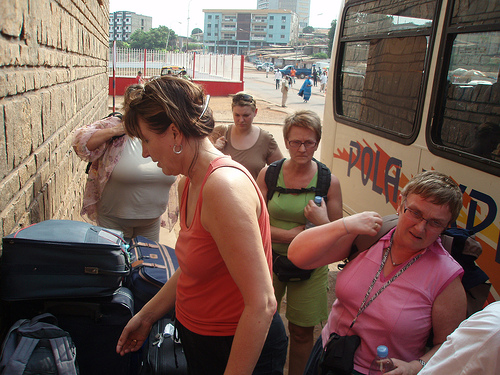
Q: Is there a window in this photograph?
A: Yes, there is a window.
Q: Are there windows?
A: Yes, there is a window.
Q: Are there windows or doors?
A: Yes, there is a window.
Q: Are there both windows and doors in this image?
A: No, there is a window but no doors.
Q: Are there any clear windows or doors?
A: Yes, there is a clear window.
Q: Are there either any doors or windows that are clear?
A: Yes, the window is clear.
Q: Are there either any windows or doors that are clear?
A: Yes, the window is clear.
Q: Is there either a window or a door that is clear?
A: Yes, the window is clear.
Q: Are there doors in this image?
A: No, there are no doors.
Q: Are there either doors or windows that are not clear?
A: No, there is a window but it is clear.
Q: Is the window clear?
A: Yes, the window is clear.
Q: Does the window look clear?
A: Yes, the window is clear.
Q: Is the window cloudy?
A: No, the window is clear.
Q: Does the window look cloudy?
A: No, the window is clear.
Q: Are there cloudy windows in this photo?
A: No, there is a window but it is clear.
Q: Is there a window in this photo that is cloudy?
A: No, there is a window but it is clear.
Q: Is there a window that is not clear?
A: No, there is a window but it is clear.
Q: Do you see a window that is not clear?
A: No, there is a window but it is clear.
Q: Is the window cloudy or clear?
A: The window is clear.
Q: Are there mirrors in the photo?
A: No, there are no mirrors.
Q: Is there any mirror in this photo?
A: No, there are no mirrors.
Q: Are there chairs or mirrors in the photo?
A: No, there are no mirrors or chairs.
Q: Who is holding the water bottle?
A: The passengers are holding the water bottle.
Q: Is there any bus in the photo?
A: Yes, there is a bus.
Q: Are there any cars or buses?
A: Yes, there is a bus.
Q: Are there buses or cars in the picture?
A: Yes, there is a bus.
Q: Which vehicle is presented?
A: The vehicle is a bus.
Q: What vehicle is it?
A: The vehicle is a bus.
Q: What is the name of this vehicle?
A: This is a bus.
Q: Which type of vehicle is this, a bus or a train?
A: This is a bus.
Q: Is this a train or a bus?
A: This is a bus.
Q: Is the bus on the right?
A: Yes, the bus is on the right of the image.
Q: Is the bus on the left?
A: No, the bus is on the right of the image.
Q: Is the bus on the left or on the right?
A: The bus is on the right of the image.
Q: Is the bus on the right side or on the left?
A: The bus is on the right of the image.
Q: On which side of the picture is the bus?
A: The bus is on the right of the image.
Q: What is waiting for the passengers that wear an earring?
A: The bus is waiting for the passengers.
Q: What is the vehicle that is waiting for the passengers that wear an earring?
A: The vehicle is a bus.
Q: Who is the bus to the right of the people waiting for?
A: The bus is waiting for the passengers.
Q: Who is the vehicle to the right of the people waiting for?
A: The bus is waiting for the passengers.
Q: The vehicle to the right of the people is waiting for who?
A: The bus is waiting for the passengers.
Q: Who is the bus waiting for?
A: The bus is waiting for the passengers.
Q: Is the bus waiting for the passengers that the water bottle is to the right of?
A: Yes, the bus is waiting for the passengers.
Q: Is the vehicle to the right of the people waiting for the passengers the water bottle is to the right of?
A: Yes, the bus is waiting for the passengers.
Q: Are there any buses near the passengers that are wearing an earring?
A: Yes, there is a bus near the passengers.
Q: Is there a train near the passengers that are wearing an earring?
A: No, there is a bus near the passengers.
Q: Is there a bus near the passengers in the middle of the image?
A: Yes, there is a bus near the passengers.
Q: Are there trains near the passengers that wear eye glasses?
A: No, there is a bus near the passengers.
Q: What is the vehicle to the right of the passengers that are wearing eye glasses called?
A: The vehicle is a bus.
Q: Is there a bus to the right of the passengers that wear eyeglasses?
A: Yes, there is a bus to the right of the passengers.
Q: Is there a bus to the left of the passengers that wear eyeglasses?
A: No, the bus is to the right of the passengers.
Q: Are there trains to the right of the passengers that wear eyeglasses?
A: No, there is a bus to the right of the passengers.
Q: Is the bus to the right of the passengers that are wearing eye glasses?
A: Yes, the bus is to the right of the passengers.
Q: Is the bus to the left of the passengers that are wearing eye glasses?
A: No, the bus is to the right of the passengers.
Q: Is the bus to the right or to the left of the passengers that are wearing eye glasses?
A: The bus is to the right of the passengers.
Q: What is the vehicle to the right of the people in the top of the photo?
A: The vehicle is a bus.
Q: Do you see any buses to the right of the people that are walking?
A: Yes, there is a bus to the right of the people.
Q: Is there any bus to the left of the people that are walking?
A: No, the bus is to the right of the people.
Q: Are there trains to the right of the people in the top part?
A: No, there is a bus to the right of the people.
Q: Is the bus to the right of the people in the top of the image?
A: Yes, the bus is to the right of the people.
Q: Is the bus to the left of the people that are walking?
A: No, the bus is to the right of the people.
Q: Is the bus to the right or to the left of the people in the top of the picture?
A: The bus is to the right of the people.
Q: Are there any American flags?
A: No, there are no American flags.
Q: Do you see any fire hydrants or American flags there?
A: No, there are no American flags or fire hydrants.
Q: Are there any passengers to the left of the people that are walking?
A: Yes, there are passengers to the left of the people.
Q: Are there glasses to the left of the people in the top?
A: No, there are passengers to the left of the people.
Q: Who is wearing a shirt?
A: The passengers are wearing a shirt.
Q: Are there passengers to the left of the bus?
A: Yes, there are passengers to the left of the bus.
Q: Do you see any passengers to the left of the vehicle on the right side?
A: Yes, there are passengers to the left of the bus.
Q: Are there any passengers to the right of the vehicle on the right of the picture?
A: No, the passengers are to the left of the bus.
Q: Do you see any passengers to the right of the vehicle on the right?
A: No, the passengers are to the left of the bus.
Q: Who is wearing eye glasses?
A: The passengers are wearing eye glasses.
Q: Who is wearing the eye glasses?
A: The passengers are wearing eye glasses.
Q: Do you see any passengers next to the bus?
A: Yes, there are passengers next to the bus.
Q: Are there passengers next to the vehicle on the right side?
A: Yes, there are passengers next to the bus.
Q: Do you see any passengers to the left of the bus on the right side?
A: Yes, there are passengers to the left of the bus.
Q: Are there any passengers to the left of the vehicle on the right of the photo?
A: Yes, there are passengers to the left of the bus.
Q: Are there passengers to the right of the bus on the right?
A: No, the passengers are to the left of the bus.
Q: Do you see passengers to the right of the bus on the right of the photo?
A: No, the passengers are to the left of the bus.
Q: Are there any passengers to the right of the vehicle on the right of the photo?
A: No, the passengers are to the left of the bus.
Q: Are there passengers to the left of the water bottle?
A: Yes, there are passengers to the left of the water bottle.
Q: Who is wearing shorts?
A: The passengers are wearing shorts.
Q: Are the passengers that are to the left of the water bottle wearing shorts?
A: Yes, the passengers are wearing shorts.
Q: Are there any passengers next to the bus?
A: Yes, there are passengers next to the bus.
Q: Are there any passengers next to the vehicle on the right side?
A: Yes, there are passengers next to the bus.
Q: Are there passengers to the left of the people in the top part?
A: Yes, there are passengers to the left of the people.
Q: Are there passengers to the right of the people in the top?
A: No, the passengers are to the left of the people.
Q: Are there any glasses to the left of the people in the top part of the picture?
A: No, there are passengers to the left of the people.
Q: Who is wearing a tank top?
A: The passengers are wearing a tank top.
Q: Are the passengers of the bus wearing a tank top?
A: Yes, the passengers are wearing a tank top.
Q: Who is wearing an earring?
A: The passengers are wearing an earring.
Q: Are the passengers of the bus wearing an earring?
A: Yes, the passengers are wearing an earring.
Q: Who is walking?
A: The people are walking.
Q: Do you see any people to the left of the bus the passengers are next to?
A: Yes, there are people to the left of the bus.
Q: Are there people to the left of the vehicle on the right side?
A: Yes, there are people to the left of the bus.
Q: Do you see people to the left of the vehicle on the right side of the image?
A: Yes, there are people to the left of the bus.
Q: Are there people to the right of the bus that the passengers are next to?
A: No, the people are to the left of the bus.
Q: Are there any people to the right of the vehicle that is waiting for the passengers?
A: No, the people are to the left of the bus.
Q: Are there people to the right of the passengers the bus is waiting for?
A: Yes, there are people to the right of the passengers.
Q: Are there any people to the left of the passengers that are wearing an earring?
A: No, the people are to the right of the passengers.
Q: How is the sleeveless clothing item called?
A: The clothing item is a tank top.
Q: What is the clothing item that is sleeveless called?
A: The clothing item is a tank top.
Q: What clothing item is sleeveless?
A: The clothing item is a tank top.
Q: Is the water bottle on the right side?
A: Yes, the water bottle is on the right of the image.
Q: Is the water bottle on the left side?
A: No, the water bottle is on the right of the image.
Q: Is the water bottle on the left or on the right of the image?
A: The water bottle is on the right of the image.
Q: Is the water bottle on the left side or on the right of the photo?
A: The water bottle is on the right of the image.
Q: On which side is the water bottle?
A: The water bottle is on the right of the image.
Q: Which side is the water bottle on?
A: The water bottle is on the right of the image.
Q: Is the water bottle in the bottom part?
A: Yes, the water bottle is in the bottom of the image.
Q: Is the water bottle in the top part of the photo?
A: No, the water bottle is in the bottom of the image.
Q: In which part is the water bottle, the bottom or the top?
A: The water bottle is in the bottom of the image.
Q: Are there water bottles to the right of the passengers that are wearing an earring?
A: Yes, there is a water bottle to the right of the passengers.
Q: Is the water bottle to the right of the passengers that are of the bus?
A: Yes, the water bottle is to the right of the passengers.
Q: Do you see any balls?
A: No, there are no balls.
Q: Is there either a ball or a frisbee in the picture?
A: No, there are no balls or frisbees.